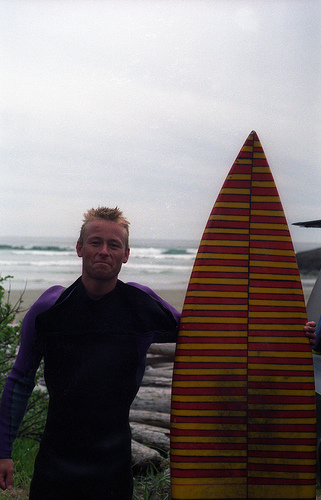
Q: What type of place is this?
A: It is a beach.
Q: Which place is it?
A: It is a beach.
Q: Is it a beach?
A: Yes, it is a beach.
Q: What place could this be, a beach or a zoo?
A: It is a beach.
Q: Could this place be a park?
A: No, it is a beach.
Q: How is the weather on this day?
A: It is cloudy.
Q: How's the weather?
A: It is cloudy.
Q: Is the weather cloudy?
A: Yes, it is cloudy.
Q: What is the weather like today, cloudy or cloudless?
A: It is cloudy.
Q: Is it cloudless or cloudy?
A: It is cloudy.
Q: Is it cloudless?
A: No, it is cloudy.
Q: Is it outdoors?
A: Yes, it is outdoors.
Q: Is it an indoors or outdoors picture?
A: It is outdoors.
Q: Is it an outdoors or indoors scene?
A: It is outdoors.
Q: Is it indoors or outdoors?
A: It is outdoors.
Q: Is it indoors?
A: No, it is outdoors.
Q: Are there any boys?
A: No, there are no boys.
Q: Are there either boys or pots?
A: No, there are no boys or pots.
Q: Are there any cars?
A: No, there are no cars.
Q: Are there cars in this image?
A: No, there are no cars.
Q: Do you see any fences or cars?
A: No, there are no cars or fences.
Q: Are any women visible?
A: No, there are no women.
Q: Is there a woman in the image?
A: No, there are no women.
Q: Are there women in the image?
A: No, there are no women.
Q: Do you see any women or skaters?
A: No, there are no women or skaters.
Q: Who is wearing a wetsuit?
A: The man is wearing a wetsuit.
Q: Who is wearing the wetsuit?
A: The man is wearing a wetsuit.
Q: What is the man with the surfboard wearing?
A: The man is wearing a wetsuit.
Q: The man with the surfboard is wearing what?
A: The man is wearing a wetsuit.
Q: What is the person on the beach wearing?
A: The man is wearing a wetsuit.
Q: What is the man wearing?
A: The man is wearing a wetsuit.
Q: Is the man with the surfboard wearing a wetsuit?
A: Yes, the man is wearing a wetsuit.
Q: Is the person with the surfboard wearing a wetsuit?
A: Yes, the man is wearing a wetsuit.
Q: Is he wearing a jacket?
A: No, the man is wearing a wetsuit.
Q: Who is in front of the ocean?
A: The man is in front of the ocean.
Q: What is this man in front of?
A: The man is in front of the ocean.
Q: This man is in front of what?
A: The man is in front of the ocean.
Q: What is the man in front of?
A: The man is in front of the ocean.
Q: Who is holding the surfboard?
A: The man is holding the surfboard.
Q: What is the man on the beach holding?
A: The man is holding the surfboard.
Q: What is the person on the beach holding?
A: The man is holding the surfboard.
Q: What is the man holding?
A: The man is holding the surfboard.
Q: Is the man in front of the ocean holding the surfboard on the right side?
A: Yes, the man is holding the surf board.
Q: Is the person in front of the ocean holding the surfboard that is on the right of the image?
A: Yes, the man is holding the surf board.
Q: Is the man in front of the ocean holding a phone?
A: No, the man is holding the surf board.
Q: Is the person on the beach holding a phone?
A: No, the man is holding the surf board.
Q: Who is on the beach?
A: The man is on the beach.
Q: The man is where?
A: The man is on the beach.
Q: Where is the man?
A: The man is on the beach.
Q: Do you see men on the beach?
A: Yes, there is a man on the beach.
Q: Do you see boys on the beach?
A: No, there is a man on the beach.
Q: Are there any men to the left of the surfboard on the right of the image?
A: Yes, there is a man to the left of the surfboard.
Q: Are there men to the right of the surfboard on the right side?
A: No, the man is to the left of the surfboard.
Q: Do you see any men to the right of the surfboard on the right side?
A: No, the man is to the left of the surfboard.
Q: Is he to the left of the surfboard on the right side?
A: Yes, the man is to the left of the surfboard.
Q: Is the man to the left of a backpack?
A: No, the man is to the left of the surfboard.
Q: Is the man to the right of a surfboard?
A: No, the man is to the left of a surfboard.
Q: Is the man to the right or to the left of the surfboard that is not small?
A: The man is to the left of the surfboard.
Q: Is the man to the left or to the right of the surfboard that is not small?
A: The man is to the left of the surfboard.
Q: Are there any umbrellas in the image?
A: No, there are no umbrellas.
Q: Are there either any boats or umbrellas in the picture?
A: No, there are no umbrellas or boats.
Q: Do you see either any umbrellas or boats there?
A: No, there are no umbrellas or boats.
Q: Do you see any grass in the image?
A: Yes, there is grass.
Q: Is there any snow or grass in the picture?
A: Yes, there is grass.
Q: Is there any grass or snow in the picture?
A: Yes, there is grass.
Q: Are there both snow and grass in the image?
A: No, there is grass but no snow.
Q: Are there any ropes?
A: No, there are no ropes.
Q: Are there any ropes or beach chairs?
A: No, there are no ropes or beach chairs.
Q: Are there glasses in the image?
A: No, there are no glasses.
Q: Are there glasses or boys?
A: No, there are no glasses or boys.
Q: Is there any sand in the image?
A: Yes, there is sand.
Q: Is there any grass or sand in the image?
A: Yes, there is sand.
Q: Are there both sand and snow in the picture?
A: No, there is sand but no snow.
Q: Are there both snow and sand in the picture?
A: No, there is sand but no snow.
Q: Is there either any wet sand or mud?
A: Yes, there is wet sand.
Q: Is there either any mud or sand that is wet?
A: Yes, the sand is wet.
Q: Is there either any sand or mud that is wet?
A: Yes, the sand is wet.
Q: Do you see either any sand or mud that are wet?
A: Yes, the sand is wet.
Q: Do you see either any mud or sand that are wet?
A: Yes, the sand is wet.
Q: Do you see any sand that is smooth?
A: Yes, there is smooth sand.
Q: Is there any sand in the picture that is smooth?
A: Yes, there is sand that is smooth.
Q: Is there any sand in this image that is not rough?
A: Yes, there is smooth sand.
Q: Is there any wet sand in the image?
A: Yes, there is wet sand.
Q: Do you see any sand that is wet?
A: Yes, there is sand that is wet.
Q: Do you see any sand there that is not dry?
A: Yes, there is wet sand.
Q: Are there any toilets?
A: No, there are no toilets.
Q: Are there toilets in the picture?
A: No, there are no toilets.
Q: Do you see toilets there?
A: No, there are no toilets.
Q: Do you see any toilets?
A: No, there are no toilets.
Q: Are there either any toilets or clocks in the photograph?
A: No, there are no toilets or clocks.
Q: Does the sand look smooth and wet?
A: Yes, the sand is smooth and wet.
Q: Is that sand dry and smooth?
A: No, the sand is smooth but wet.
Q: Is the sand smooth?
A: Yes, the sand is smooth.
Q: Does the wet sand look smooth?
A: Yes, the sand is smooth.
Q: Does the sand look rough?
A: No, the sand is smooth.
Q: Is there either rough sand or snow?
A: No, there is sand but it is smooth.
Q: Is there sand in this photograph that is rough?
A: No, there is sand but it is smooth.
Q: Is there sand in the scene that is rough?
A: No, there is sand but it is smooth.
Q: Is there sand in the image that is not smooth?
A: No, there is sand but it is smooth.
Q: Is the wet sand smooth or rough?
A: The sand is smooth.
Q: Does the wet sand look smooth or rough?
A: The sand is smooth.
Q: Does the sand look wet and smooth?
A: Yes, the sand is wet and smooth.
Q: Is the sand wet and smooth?
A: Yes, the sand is wet and smooth.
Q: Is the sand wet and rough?
A: No, the sand is wet but smooth.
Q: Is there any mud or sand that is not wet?
A: No, there is sand but it is wet.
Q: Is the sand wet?
A: Yes, the sand is wet.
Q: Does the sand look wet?
A: Yes, the sand is wet.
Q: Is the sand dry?
A: No, the sand is wet.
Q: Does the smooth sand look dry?
A: No, the sand is wet.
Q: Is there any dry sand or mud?
A: No, there is sand but it is wet.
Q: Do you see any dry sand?
A: No, there is sand but it is wet.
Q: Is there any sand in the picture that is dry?
A: No, there is sand but it is wet.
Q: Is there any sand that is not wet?
A: No, there is sand but it is wet.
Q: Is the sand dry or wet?
A: The sand is wet.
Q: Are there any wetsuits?
A: Yes, there is a wetsuit.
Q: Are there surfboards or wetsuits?
A: Yes, there is a wetsuit.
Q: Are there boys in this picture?
A: No, there are no boys.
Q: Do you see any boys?
A: No, there are no boys.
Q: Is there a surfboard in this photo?
A: Yes, there is a surfboard.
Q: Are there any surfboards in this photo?
A: Yes, there is a surfboard.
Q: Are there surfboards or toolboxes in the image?
A: Yes, there is a surfboard.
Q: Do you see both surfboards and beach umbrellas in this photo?
A: No, there is a surfboard but no beach umbrellas.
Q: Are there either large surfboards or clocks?
A: Yes, there is a large surfboard.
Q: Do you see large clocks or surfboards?
A: Yes, there is a large surfboard.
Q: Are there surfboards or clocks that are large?
A: Yes, the surfboard is large.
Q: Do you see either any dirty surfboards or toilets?
A: Yes, there is a dirty surfboard.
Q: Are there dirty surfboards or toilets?
A: Yes, there is a dirty surfboard.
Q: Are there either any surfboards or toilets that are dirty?
A: Yes, the surfboard is dirty.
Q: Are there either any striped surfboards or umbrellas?
A: Yes, there is a striped surfboard.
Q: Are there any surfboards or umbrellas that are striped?
A: Yes, the surfboard is striped.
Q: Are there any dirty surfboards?
A: Yes, there is a dirty surfboard.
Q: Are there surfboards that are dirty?
A: Yes, there is a surfboard that is dirty.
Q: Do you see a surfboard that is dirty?
A: Yes, there is a surfboard that is dirty.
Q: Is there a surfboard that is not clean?
A: Yes, there is a dirty surfboard.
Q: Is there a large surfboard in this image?
A: Yes, there is a large surfboard.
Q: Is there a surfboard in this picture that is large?
A: Yes, there is a surfboard that is large.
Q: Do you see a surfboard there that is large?
A: Yes, there is a surfboard that is large.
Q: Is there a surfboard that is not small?
A: Yes, there is a large surfboard.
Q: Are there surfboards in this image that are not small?
A: Yes, there is a large surfboard.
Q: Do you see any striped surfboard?
A: Yes, there is a striped surfboard.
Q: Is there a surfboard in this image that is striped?
A: Yes, there is a surfboard that is striped.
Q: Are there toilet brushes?
A: No, there are no toilet brushes.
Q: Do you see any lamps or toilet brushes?
A: No, there are no toilet brushes or lamps.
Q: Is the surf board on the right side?
A: Yes, the surf board is on the right of the image.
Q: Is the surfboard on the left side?
A: No, the surfboard is on the right of the image.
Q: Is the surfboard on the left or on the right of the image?
A: The surfboard is on the right of the image.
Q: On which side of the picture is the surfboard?
A: The surfboard is on the right of the image.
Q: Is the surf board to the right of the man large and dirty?
A: Yes, the surfboard is large and dirty.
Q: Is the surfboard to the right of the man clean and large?
A: No, the surfboard is large but dirty.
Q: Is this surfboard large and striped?
A: Yes, the surfboard is large and striped.